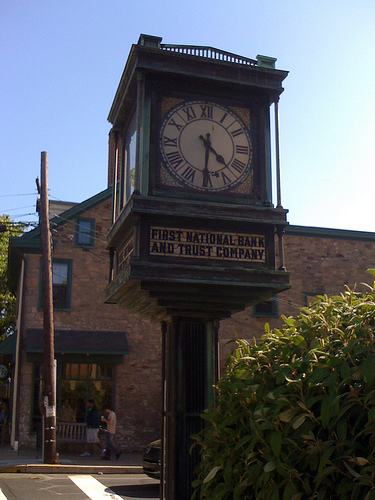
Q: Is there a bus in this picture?
A: No, there are no buses.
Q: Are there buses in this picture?
A: No, there are no buses.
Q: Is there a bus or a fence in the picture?
A: No, there are no buses or fences.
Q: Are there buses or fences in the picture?
A: No, there are no buses or fences.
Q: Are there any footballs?
A: No, there are no footballs.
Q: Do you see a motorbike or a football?
A: No, there are no footballs or motorcycles.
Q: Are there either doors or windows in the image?
A: Yes, there is a window.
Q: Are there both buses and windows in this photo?
A: No, there is a window but no buses.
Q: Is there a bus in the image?
A: No, there are no buses.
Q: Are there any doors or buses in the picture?
A: No, there are no buses or doors.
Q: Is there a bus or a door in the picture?
A: No, there are no buses or doors.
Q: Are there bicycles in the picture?
A: No, there are no bicycles.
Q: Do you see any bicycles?
A: No, there are no bicycles.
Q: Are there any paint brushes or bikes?
A: No, there are no bikes or paint brushes.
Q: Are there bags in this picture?
A: No, there are no bags.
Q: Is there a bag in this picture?
A: No, there are no bags.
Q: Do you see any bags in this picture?
A: No, there are no bags.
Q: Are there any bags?
A: No, there are no bags.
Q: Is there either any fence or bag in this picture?
A: No, there are no bags or fences.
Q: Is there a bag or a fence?
A: No, there are no bags or fences.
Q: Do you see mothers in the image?
A: No, there are no mothers.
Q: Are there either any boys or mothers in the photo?
A: No, there are no mothers or boys.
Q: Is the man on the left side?
A: Yes, the man is on the left of the image.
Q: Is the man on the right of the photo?
A: No, the man is on the left of the image.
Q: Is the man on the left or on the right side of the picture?
A: The man is on the left of the image.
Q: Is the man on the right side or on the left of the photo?
A: The man is on the left of the image.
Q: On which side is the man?
A: The man is on the left of the image.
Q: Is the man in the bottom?
A: Yes, the man is in the bottom of the image.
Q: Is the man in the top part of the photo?
A: No, the man is in the bottom of the image.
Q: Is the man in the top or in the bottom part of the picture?
A: The man is in the bottom of the image.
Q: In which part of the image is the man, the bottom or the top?
A: The man is in the bottom of the image.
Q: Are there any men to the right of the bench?
A: Yes, there is a man to the right of the bench.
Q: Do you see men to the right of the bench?
A: Yes, there is a man to the right of the bench.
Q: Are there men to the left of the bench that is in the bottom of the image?
A: No, the man is to the right of the bench.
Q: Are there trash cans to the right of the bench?
A: No, there is a man to the right of the bench.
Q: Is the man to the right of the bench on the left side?
A: Yes, the man is to the right of the bench.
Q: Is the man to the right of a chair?
A: No, the man is to the right of the bench.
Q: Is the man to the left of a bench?
A: No, the man is to the right of a bench.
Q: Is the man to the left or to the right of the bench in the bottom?
A: The man is to the right of the bench.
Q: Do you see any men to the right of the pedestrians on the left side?
A: Yes, there is a man to the right of the pedestrians.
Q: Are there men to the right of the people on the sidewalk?
A: Yes, there is a man to the right of the pedestrians.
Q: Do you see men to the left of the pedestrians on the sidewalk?
A: No, the man is to the right of the pedestrians.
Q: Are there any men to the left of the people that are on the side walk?
A: No, the man is to the right of the pedestrians.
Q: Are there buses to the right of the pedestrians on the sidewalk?
A: No, there is a man to the right of the pedestrians.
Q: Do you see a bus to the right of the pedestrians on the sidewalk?
A: No, there is a man to the right of the pedestrians.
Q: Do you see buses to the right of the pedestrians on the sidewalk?
A: No, there is a man to the right of the pedestrians.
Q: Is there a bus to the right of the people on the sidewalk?
A: No, there is a man to the right of the pedestrians.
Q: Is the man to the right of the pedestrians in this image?
A: Yes, the man is to the right of the pedestrians.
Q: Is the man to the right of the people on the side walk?
A: Yes, the man is to the right of the pedestrians.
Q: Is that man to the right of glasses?
A: No, the man is to the right of the pedestrians.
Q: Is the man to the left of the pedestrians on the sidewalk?
A: No, the man is to the right of the pedestrians.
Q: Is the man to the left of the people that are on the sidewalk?
A: No, the man is to the right of the pedestrians.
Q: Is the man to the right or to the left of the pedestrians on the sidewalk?
A: The man is to the right of the pedestrians.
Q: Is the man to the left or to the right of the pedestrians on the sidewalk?
A: The man is to the right of the pedestrians.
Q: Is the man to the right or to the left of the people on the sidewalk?
A: The man is to the right of the pedestrians.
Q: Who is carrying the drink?
A: The man is carrying the drink.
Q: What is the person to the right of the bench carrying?
A: The man is carrying a drink.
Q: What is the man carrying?
A: The man is carrying a drink.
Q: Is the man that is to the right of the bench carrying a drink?
A: Yes, the man is carrying a drink.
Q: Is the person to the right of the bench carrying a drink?
A: Yes, the man is carrying a drink.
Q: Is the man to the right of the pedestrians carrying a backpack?
A: No, the man is carrying a drink.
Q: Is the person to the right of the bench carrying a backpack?
A: No, the man is carrying a drink.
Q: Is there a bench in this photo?
A: Yes, there is a bench.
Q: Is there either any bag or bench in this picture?
A: Yes, there is a bench.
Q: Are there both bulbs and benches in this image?
A: No, there is a bench but no light bulbs.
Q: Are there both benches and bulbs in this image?
A: No, there is a bench but no light bulbs.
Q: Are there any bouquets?
A: No, there are no bouquets.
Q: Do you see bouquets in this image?
A: No, there are no bouquets.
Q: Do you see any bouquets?
A: No, there are no bouquets.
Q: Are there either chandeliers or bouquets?
A: No, there are no bouquets or chandeliers.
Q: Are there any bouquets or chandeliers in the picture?
A: No, there are no bouquets or chandeliers.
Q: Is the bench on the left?
A: Yes, the bench is on the left of the image.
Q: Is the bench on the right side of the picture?
A: No, the bench is on the left of the image.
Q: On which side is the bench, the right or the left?
A: The bench is on the left of the image.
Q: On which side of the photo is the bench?
A: The bench is on the left of the image.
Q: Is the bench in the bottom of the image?
A: Yes, the bench is in the bottom of the image.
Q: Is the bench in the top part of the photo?
A: No, the bench is in the bottom of the image.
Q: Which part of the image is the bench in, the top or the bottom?
A: The bench is in the bottom of the image.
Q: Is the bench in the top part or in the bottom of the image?
A: The bench is in the bottom of the image.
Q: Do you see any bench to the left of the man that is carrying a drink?
A: Yes, there is a bench to the left of the man.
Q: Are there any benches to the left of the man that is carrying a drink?
A: Yes, there is a bench to the left of the man.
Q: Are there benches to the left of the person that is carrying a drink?
A: Yes, there is a bench to the left of the man.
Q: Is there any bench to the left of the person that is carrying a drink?
A: Yes, there is a bench to the left of the man.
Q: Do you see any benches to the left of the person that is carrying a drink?
A: Yes, there is a bench to the left of the man.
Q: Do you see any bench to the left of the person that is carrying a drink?
A: Yes, there is a bench to the left of the man.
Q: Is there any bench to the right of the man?
A: No, the bench is to the left of the man.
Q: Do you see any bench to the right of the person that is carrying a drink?
A: No, the bench is to the left of the man.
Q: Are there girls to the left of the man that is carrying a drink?
A: No, there is a bench to the left of the man.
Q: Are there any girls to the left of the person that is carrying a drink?
A: No, there is a bench to the left of the man.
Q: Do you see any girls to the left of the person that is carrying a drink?
A: No, there is a bench to the left of the man.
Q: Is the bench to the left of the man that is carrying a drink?
A: Yes, the bench is to the left of the man.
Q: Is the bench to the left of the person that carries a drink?
A: Yes, the bench is to the left of the man.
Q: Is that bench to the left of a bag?
A: No, the bench is to the left of the man.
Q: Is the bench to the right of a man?
A: No, the bench is to the left of a man.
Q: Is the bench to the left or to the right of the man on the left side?
A: The bench is to the left of the man.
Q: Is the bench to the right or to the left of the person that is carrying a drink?
A: The bench is to the left of the man.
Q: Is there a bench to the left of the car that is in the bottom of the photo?
A: Yes, there is a bench to the left of the car.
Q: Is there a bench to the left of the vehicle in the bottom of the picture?
A: Yes, there is a bench to the left of the car.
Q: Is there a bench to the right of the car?
A: No, the bench is to the left of the car.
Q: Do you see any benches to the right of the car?
A: No, the bench is to the left of the car.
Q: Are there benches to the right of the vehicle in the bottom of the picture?
A: No, the bench is to the left of the car.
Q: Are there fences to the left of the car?
A: No, there is a bench to the left of the car.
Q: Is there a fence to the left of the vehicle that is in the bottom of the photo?
A: No, there is a bench to the left of the car.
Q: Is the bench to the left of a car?
A: Yes, the bench is to the left of a car.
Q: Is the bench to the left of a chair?
A: No, the bench is to the left of a car.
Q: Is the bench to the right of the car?
A: No, the bench is to the left of the car.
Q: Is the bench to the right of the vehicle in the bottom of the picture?
A: No, the bench is to the left of the car.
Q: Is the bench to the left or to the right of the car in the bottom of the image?
A: The bench is to the left of the car.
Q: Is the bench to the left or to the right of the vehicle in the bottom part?
A: The bench is to the left of the car.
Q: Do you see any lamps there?
A: No, there are no lamps.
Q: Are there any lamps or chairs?
A: No, there are no lamps or chairs.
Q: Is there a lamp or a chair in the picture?
A: No, there are no lamps or chairs.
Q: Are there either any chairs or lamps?
A: No, there are no lamps or chairs.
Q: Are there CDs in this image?
A: No, there are no cds.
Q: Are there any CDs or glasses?
A: No, there are no CDs or glasses.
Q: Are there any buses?
A: No, there are no buses.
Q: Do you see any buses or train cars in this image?
A: No, there are no buses or train cars.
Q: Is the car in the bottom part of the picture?
A: Yes, the car is in the bottom of the image.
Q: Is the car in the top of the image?
A: No, the car is in the bottom of the image.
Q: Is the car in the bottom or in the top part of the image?
A: The car is in the bottom of the image.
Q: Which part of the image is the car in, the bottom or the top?
A: The car is in the bottom of the image.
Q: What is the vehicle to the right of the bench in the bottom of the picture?
A: The vehicle is a car.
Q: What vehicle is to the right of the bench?
A: The vehicle is a car.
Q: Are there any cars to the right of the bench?
A: Yes, there is a car to the right of the bench.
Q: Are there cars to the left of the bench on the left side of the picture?
A: No, the car is to the right of the bench.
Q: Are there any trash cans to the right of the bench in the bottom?
A: No, there is a car to the right of the bench.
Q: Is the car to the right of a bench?
A: Yes, the car is to the right of a bench.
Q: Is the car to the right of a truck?
A: No, the car is to the right of a bench.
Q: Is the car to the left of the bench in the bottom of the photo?
A: No, the car is to the right of the bench.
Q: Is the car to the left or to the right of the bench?
A: The car is to the right of the bench.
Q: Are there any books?
A: No, there are no books.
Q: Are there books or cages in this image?
A: No, there are no books or cages.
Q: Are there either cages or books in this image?
A: No, there are no books or cages.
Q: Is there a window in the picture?
A: Yes, there is a window.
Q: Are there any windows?
A: Yes, there is a window.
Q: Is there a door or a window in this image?
A: Yes, there is a window.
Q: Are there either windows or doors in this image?
A: Yes, there is a window.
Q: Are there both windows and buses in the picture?
A: No, there is a window but no buses.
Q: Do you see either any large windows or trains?
A: Yes, there is a large window.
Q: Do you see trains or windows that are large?
A: Yes, the window is large.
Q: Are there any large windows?
A: Yes, there is a large window.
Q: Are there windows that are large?
A: Yes, there is a window that is large.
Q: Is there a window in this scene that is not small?
A: Yes, there is a large window.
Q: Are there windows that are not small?
A: Yes, there is a large window.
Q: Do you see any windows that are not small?
A: Yes, there is a large window.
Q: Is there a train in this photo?
A: No, there are no trains.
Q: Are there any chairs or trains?
A: No, there are no trains or chairs.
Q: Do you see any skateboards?
A: No, there are no skateboards.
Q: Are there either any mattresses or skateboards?
A: No, there are no skateboards or mattresses.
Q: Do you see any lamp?
A: No, there are no lamps.